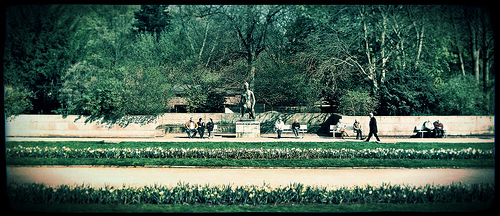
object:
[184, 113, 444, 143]
people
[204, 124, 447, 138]
bench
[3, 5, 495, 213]
park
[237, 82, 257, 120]
statue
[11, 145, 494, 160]
flowers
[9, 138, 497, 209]
row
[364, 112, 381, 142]
man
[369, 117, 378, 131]
jacket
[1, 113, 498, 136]
wall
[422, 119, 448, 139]
sitters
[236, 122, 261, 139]
stand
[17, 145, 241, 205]
group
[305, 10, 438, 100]
branches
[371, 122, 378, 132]
black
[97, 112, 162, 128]
shade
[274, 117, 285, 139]
person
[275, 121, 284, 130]
shirt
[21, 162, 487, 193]
pond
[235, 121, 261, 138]
pedestal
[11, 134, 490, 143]
sidewalk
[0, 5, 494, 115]
tree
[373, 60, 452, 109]
leaves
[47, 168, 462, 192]
water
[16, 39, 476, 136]
background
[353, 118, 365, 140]
man